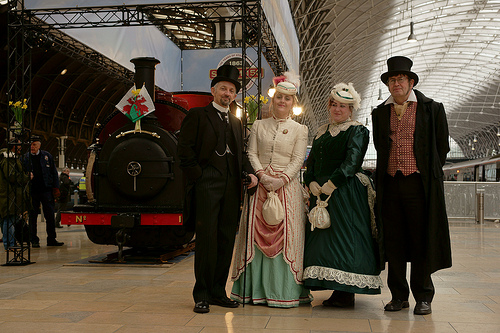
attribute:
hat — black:
[378, 52, 422, 85]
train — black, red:
[56, 56, 243, 266]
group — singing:
[170, 54, 457, 316]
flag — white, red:
[118, 76, 162, 138]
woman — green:
[303, 76, 400, 317]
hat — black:
[371, 52, 424, 86]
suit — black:
[173, 92, 248, 312]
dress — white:
[244, 115, 310, 309]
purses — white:
[256, 171, 338, 239]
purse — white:
[259, 188, 290, 230]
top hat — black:
[207, 61, 242, 91]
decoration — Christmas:
[110, 83, 155, 120]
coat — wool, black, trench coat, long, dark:
[369, 88, 456, 270]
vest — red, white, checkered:
[389, 103, 419, 175]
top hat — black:
[377, 54, 422, 88]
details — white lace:
[294, 253, 392, 295]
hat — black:
[204, 58, 246, 99]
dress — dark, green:
[300, 115, 388, 303]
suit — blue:
[18, 148, 65, 242]